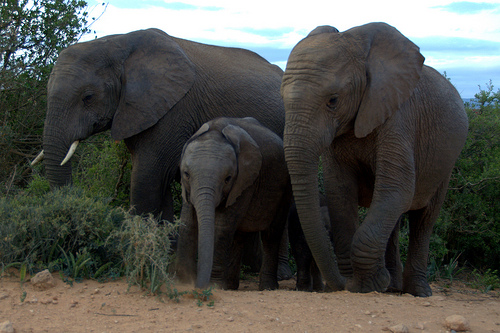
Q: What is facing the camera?
A: The mommy daddy and baby elephant.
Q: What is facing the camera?
A: The grey baby elephant.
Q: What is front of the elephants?
A: The dirt.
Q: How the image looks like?
A: Good.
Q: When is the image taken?
A: Elephants are standing.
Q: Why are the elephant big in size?
A: Breed.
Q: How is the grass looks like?
A: Tall.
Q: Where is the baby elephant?
A: In the middle.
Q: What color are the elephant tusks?
A: White.